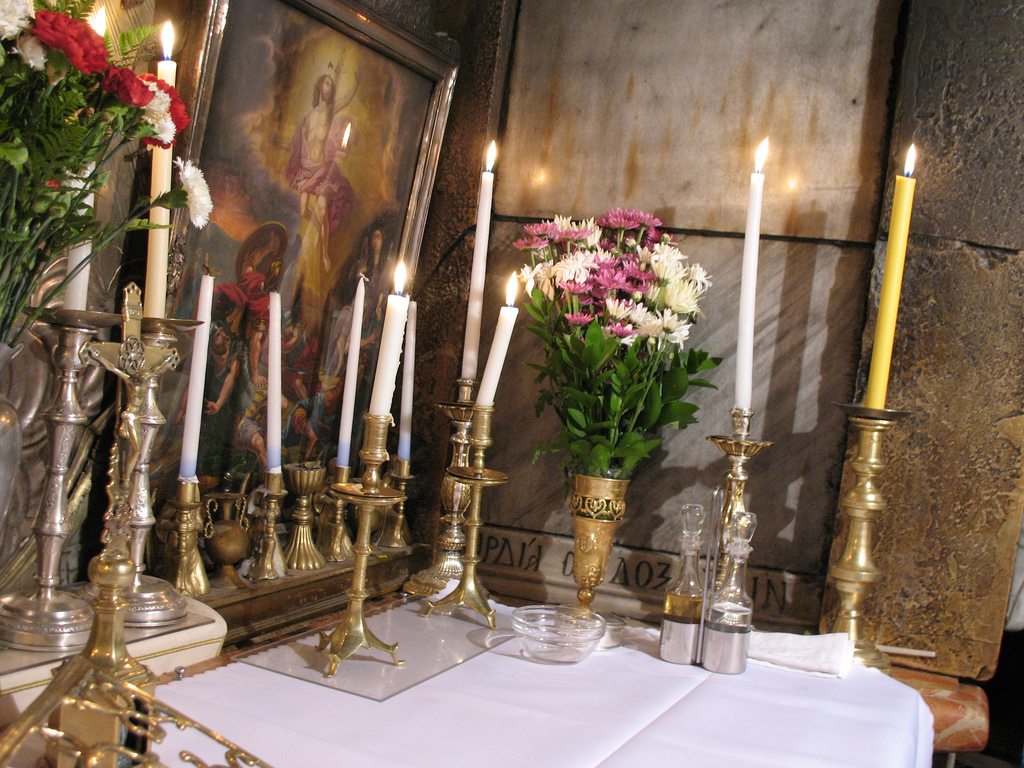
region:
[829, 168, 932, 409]
a long yellow candle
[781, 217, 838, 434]
the shadow of a candle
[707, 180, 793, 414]
a long white candle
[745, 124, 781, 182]
the flame of a candle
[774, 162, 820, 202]
the reflection of the flame of a candle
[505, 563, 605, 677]
a small glass bowl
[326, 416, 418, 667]
the holder of a candle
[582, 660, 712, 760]
a crack on the table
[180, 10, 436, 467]
a picture on the wall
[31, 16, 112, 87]
a rose that is red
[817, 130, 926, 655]
yellow candle in a gold candlestick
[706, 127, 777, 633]
white candle in a gold candlestick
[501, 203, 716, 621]
purple and white flowers in a gold vase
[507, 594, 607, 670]
clear glass bowl on a white tablecloth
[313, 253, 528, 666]
two gold candlesticks with white candles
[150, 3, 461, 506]
religious picture in a gold frame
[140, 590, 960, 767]
white tablecloth on a table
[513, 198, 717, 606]
bouquet of flowers in a vase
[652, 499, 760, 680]
two small glass vials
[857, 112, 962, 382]
candle on a table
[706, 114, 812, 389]
candle on a table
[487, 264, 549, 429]
candle on a table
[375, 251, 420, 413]
candle on a table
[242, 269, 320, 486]
candle on a table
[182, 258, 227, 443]
candle on a table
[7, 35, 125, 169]
flowers near a table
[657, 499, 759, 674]
Jars with liquid in them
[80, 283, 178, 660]
A crucifix with Jesus on it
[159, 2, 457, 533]
A painting with a silver frame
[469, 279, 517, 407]
A candle that is leaning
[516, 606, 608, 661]
A clear bowl sitting on an altar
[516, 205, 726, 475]
Flowers in a vase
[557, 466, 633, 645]
A gold vase that has flowers in it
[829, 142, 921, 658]
A tall candle in a candlestick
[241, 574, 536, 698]
A small plate of glass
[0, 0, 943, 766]
Religious altar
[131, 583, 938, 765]
White cloth on the table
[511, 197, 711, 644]
Pink and white flowers in a vase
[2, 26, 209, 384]
Red and white flowers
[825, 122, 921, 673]
Yellow candle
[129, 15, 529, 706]
Candles in front of the picture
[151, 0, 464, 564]
Religious picture on the wall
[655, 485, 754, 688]
Cruets on the table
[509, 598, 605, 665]
Small glass bowl on the table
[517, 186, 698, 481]
white and pink flowers in gold vase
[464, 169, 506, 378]
A candle on a holder.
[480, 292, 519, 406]
A candle on a holder.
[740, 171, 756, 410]
A candle on a holder.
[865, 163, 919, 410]
A candle on a holder.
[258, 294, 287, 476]
A candle on a holder.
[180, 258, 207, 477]
A candle on a holder.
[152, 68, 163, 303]
A candle on a holder.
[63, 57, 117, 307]
A candle on a holder.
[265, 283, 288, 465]
A candle on a holder.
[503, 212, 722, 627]
Purple and white flowers in a vase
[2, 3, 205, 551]
Red and white flowers in a vase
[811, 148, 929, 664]
A lit candle in a holder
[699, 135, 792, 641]
A lit candle in a holder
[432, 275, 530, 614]
A lit candle in a holder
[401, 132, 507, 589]
A lit candle in a holder